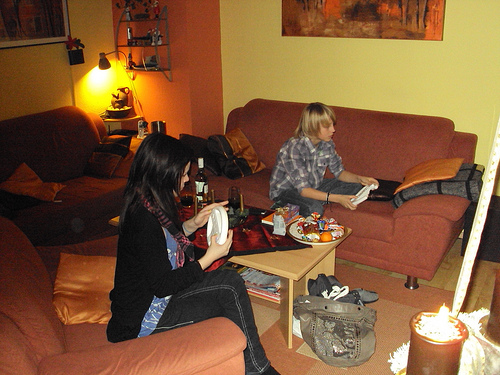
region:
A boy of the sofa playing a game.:
[272, 99, 360, 206]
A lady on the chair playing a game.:
[112, 129, 251, 323]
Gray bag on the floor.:
[302, 272, 388, 361]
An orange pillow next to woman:
[48, 241, 118, 328]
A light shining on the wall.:
[71, 40, 125, 80]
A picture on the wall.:
[260, 4, 453, 70]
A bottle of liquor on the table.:
[184, 155, 206, 208]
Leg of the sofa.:
[393, 266, 440, 296]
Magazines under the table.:
[241, 275, 277, 306]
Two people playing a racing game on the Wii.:
[104, 104, 381, 372]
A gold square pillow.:
[54, 250, 115, 322]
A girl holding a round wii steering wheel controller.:
[102, 132, 278, 371]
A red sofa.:
[169, 97, 480, 290]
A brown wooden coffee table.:
[107, 187, 353, 345]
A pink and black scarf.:
[134, 172, 196, 265]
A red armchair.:
[0, 212, 255, 374]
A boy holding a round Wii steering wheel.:
[269, 101, 379, 239]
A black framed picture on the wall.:
[1, 0, 72, 53]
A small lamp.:
[93, 49, 131, 76]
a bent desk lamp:
[92, 48, 132, 77]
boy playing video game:
[272, 107, 374, 223]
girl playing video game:
[102, 133, 278, 373]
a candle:
[410, 303, 467, 373]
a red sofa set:
[0, 93, 477, 374]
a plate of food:
[293, 209, 344, 245]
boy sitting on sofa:
[272, 103, 374, 218]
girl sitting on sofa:
[112, 137, 277, 374]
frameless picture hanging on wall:
[280, 2, 446, 42]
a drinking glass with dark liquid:
[225, 185, 240, 208]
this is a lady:
[127, 129, 217, 324]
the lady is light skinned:
[209, 239, 232, 259]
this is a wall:
[396, 48, 473, 93]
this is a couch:
[377, 114, 456, 250]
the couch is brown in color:
[362, 110, 410, 155]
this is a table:
[270, 250, 321, 290]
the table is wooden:
[272, 255, 308, 278]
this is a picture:
[283, 12, 440, 36]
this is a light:
[87, 53, 118, 82]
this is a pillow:
[213, 132, 253, 177]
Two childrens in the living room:
[6, 1, 478, 349]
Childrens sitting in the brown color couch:
[31, 125, 398, 255]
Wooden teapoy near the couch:
[261, 257, 302, 284]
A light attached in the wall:
[96, 48, 126, 79]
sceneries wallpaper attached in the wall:
[273, 0, 448, 43]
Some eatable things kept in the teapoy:
[293, 213, 345, 246]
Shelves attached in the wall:
[118, 8, 177, 73]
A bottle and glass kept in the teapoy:
[194, 157, 238, 199]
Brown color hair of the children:
[297, 102, 338, 130]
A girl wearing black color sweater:
[123, 213, 156, 295]